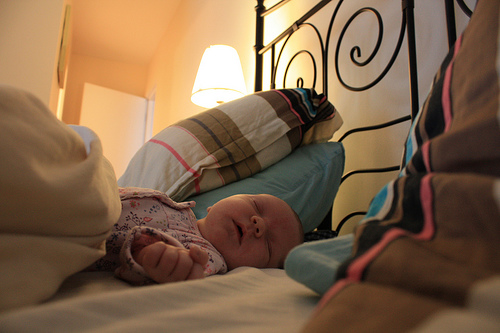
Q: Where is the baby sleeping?
A: Bed.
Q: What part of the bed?
A: Headboard.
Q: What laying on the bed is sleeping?
A: The baby.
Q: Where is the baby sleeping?
A: The bed.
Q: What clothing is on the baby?
A: The pajamas.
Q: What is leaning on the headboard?
A: The pillows.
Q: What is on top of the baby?
A: The blanket.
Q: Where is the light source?
A: Behind the pillow.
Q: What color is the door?
A: White.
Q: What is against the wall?
A: The headboard.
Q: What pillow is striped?
A: The top pillow.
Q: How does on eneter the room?
A: The door.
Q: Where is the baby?
A: Bed.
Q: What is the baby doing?
A: Sleeping.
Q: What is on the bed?
A: Headboard.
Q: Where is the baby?
A: Bed.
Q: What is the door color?
A: White.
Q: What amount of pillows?
A: Two.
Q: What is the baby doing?
A: Sleeping.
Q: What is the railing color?
A: Black.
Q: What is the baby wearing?
A: Outfit.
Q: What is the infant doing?
A: Sleeping.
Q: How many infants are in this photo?
A: One.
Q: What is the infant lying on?
A: A bed.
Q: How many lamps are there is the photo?
A: One.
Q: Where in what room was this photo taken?
A: A bedroom.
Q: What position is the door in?
A: It is open.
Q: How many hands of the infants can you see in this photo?
A: One.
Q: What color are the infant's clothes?
A: Pink.